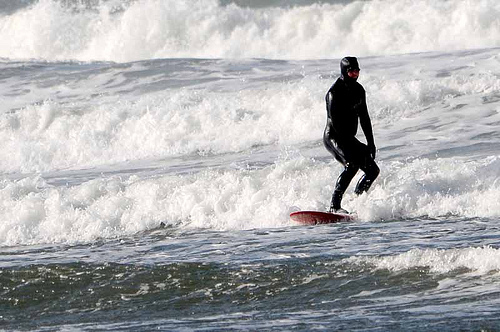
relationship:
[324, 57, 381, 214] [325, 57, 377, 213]
person in full wet suit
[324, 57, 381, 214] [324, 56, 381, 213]
person in black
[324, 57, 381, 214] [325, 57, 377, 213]
person in full body wet suit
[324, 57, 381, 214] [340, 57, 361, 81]
person wearing wet suit hood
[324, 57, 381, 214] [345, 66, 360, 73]
person wearing googles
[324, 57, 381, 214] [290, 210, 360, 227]
person on top of a surfboard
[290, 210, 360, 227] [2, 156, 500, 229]
red surfboard riding waves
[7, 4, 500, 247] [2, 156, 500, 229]
white caps on top of waves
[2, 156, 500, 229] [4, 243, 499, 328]
waves rolling into beach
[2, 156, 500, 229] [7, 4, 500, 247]
waves with white caps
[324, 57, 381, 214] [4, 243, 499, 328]
surf boarder coming onto beach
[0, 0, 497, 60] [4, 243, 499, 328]
waves rolls into beach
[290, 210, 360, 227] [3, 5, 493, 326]
surfboard in water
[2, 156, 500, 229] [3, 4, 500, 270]
waves that have white foam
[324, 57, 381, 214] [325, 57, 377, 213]
person in black wet suit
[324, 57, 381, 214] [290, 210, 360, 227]
person standing on a surfboard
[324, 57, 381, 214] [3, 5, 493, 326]
person surfing on water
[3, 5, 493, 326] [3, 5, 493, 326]
ocean has grey water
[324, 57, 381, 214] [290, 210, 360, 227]
person standing on surfboard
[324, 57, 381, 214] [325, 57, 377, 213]
person wearing wet suit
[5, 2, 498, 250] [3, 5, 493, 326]
waves in threes hit ocean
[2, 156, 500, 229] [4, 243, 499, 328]
waves are crashing down on beach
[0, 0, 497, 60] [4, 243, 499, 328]
waves crashing down on beach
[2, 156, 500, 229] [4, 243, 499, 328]
wave crashing down on beach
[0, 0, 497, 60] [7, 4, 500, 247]
waves builds up speed and white caps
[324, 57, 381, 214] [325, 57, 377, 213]
person has on black wet suit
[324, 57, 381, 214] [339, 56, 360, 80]
person has goggles on h head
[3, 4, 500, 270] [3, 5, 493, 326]
white foam in water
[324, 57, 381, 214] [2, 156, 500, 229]
person surfing on waves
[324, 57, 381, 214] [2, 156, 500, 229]
person surfing some nice waves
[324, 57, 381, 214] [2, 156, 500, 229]
person surfing awesome waves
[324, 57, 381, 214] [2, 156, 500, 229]
person surfing ocean waves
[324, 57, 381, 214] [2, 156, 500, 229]
person surfing beautiful waves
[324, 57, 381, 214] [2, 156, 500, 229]
person surfing some great waves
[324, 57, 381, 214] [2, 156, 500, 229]
person surfing nice ocea waves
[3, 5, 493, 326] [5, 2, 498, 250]
ocean has really nice waves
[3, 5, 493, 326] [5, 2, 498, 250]
ocean has beautiful waves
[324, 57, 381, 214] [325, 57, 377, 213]
person surfing in a dark wet suit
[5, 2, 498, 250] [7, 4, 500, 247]
waves with white caps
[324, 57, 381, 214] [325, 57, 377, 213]
person wearing long black wet suit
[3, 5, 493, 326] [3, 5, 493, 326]
ocean has waves in water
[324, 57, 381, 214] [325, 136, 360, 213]
person surfing with leg up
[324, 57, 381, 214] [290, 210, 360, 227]
person has left leg on surfboard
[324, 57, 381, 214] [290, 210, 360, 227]
person has white shoes on surfboard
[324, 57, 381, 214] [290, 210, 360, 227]
person wears hat while on surfboard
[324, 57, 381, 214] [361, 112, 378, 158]
person holds right leg with arm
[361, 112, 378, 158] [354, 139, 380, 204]
arm holds on to left leg